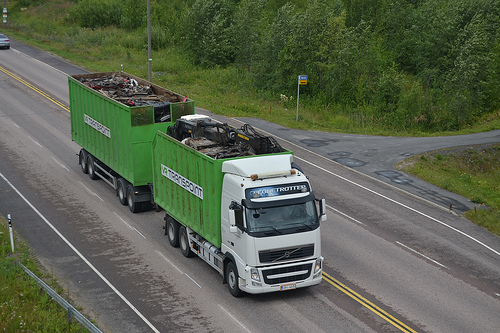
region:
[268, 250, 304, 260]
grill on the truck.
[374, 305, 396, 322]
yellow lines on road.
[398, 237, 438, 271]
white lines on road.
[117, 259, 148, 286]
water on the road.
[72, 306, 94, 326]
railing near the road.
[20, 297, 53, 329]
weeds near the road.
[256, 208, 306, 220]
windshield on the truck.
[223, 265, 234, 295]
wheel on the bus.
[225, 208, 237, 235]
mirror on the bus.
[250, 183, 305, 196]
words on the truck.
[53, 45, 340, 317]
a truck travelling down the highway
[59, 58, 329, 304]
a truck pulling two trailers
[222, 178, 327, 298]
the cab of a truck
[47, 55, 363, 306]
a truck carrying scrap metal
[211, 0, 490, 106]
the foliage and trees and shrubs beside a highway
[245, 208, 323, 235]
the windshield of a truck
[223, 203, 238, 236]
the side mirror of a truck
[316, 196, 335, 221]
the side mirror of a truck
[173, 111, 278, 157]
a pile of scrap metal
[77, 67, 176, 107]
a pile of scrap metal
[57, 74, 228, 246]
the truck container is green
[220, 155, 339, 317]
the truck is white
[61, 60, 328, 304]
a truck is pulling a green trailer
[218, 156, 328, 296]
the white cab has a white air dam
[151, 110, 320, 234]
the truck is hauling large pieces of metal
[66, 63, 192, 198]
the trailer is halling scrap metal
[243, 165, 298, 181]
amber lights are on the sides of the air dam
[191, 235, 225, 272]
fuel tanks are on the side of the truck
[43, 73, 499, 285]
the highway has a side road near the truck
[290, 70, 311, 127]
a sign is on a pole on the highway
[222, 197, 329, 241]
the truck has white side mirrors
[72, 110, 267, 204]
white signs are on the side of the green bins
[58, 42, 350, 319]
Truck on the road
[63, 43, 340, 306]
Green and white truck on the road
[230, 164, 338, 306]
White and black front of a truck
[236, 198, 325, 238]
Truck windshield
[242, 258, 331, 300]
Two headlights on a truck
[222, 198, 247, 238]
White side mirror on a truck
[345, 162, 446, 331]
Road with yellow and white lines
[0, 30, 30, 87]
Partial back of a small car on the road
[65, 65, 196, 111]
Container full of stuff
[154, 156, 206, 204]
Black writing on the side of a container